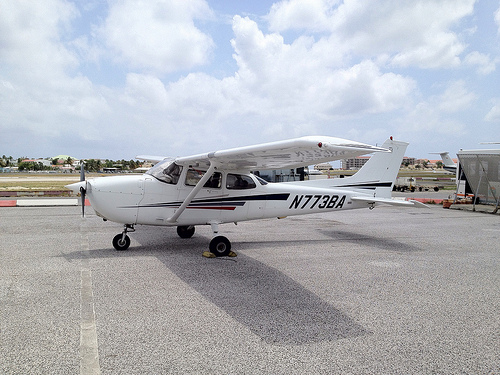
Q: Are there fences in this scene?
A: No, there are no fences.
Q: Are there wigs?
A: No, there are no wigs.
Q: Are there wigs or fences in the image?
A: No, there are no wigs or fences.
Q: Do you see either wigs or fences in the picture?
A: No, there are no wigs or fences.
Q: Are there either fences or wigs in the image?
A: No, there are no wigs or fences.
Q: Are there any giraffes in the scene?
A: No, there are no giraffes.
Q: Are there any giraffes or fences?
A: No, there are no giraffes or fences.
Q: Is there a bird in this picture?
A: No, there are no birds.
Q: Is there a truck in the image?
A: No, there are no trucks.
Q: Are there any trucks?
A: No, there are no trucks.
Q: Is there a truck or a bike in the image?
A: No, there are no trucks or bikes.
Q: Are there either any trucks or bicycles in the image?
A: No, there are no trucks or bicycles.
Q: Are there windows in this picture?
A: Yes, there is a window.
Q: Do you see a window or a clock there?
A: Yes, there is a window.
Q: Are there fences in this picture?
A: No, there are no fences.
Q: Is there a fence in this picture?
A: No, there are no fences.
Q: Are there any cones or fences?
A: No, there are no fences or cones.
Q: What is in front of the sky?
A: The clouds are in front of the sky.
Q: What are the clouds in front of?
A: The clouds are in front of the sky.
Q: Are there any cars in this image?
A: No, there are no cars.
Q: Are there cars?
A: No, there are no cars.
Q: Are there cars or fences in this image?
A: No, there are no cars or fences.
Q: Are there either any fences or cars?
A: No, there are no cars or fences.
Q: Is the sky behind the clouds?
A: Yes, the sky is behind the clouds.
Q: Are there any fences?
A: No, there are no fences.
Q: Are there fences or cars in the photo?
A: No, there are no fences or cars.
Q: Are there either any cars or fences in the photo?
A: No, there are no fences or cars.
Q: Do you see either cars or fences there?
A: No, there are no fences or cars.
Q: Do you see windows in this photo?
A: Yes, there is a window.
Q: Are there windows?
A: Yes, there is a window.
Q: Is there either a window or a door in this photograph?
A: Yes, there is a window.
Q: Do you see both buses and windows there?
A: No, there is a window but no buses.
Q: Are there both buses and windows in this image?
A: No, there is a window but no buses.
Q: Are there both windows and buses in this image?
A: No, there is a window but no buses.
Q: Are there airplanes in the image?
A: Yes, there is an airplane.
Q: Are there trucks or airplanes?
A: Yes, there is an airplane.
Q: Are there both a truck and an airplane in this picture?
A: No, there is an airplane but no trucks.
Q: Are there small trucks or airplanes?
A: Yes, there is a small airplane.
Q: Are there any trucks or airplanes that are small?
A: Yes, the airplane is small.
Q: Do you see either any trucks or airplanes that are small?
A: Yes, the airplane is small.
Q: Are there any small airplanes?
A: Yes, there is a small airplane.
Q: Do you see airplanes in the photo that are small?
A: Yes, there is an airplane that is small.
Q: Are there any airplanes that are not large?
A: Yes, there is a small airplane.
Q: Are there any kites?
A: No, there are no kites.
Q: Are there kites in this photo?
A: No, there are no kites.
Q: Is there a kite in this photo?
A: No, there are no kites.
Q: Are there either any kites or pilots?
A: No, there are no kites or pilots.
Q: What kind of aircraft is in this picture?
A: The aircraft is an airplane.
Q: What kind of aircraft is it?
A: The aircraft is an airplane.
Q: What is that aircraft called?
A: This is an airplane.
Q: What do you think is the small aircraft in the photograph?
A: The aircraft is an airplane.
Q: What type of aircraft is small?
A: The aircraft is an airplane.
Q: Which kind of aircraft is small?
A: The aircraft is an airplane.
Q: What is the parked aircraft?
A: The aircraft is an airplane.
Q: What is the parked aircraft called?
A: The aircraft is an airplane.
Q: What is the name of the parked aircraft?
A: The aircraft is an airplane.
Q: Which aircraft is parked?
A: The aircraft is an airplane.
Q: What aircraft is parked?
A: The aircraft is an airplane.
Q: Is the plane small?
A: Yes, the plane is small.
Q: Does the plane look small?
A: Yes, the plane is small.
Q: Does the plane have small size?
A: Yes, the plane is small.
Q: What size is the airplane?
A: The airplane is small.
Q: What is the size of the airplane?
A: The airplane is small.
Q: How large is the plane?
A: The plane is small.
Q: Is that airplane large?
A: No, the airplane is small.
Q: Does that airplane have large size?
A: No, the airplane is small.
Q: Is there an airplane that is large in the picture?
A: No, there is an airplane but it is small.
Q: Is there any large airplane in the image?
A: No, there is an airplane but it is small.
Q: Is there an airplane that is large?
A: No, there is an airplane but it is small.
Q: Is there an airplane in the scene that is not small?
A: No, there is an airplane but it is small.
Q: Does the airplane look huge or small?
A: The airplane is small.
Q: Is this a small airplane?
A: Yes, this is a small airplane.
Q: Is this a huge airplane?
A: No, this is a small airplane.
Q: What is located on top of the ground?
A: The airplane is on top of the ground.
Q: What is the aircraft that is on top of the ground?
A: The aircraft is an airplane.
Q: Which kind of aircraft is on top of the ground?
A: The aircraft is an airplane.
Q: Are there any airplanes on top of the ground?
A: Yes, there is an airplane on top of the ground.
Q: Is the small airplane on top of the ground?
A: Yes, the airplane is on top of the ground.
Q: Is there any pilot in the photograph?
A: No, there are no pilots.